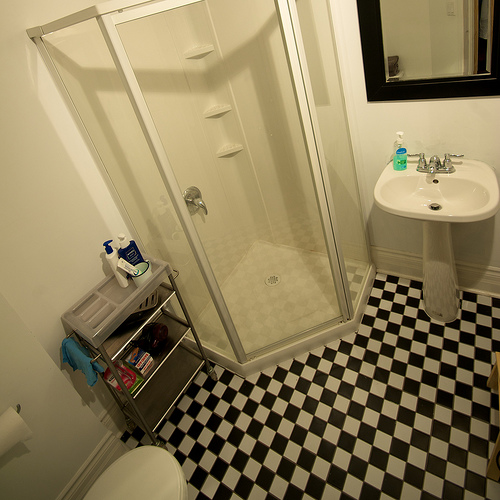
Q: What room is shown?
A: Bathroom.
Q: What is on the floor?
A: Tile.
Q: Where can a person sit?
A: Toilet.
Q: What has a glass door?
A: Shower.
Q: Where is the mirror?
A: Above the sink.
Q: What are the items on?
A: Shelf.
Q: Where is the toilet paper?
A: Hanging on the wall.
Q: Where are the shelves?
A: Back corner of the shower.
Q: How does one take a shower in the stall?
A: Standing up.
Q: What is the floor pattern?
A: Checkered.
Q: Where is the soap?
A: On sink.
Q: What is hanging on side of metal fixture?
A: Towel.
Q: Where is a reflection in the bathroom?
A: Mirror.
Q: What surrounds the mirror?
A: Black frame.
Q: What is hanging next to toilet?
A: Paper.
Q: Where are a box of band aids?
A: Shower caddy.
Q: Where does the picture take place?
A: In a bathroom.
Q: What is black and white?
A: Tiles on floor.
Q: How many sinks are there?
A: One.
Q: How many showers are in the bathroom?
A: One.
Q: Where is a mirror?
A: On the wall.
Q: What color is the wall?
A: White.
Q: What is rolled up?
A: Toilet paper.